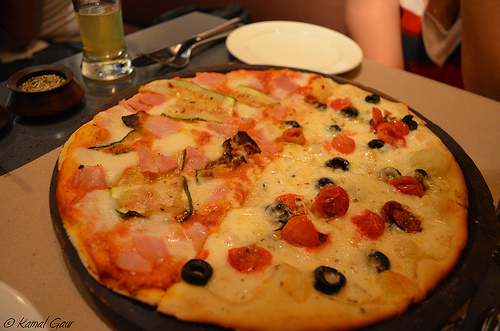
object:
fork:
[137, 32, 230, 67]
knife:
[128, 18, 240, 68]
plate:
[223, 20, 362, 76]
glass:
[75, 2, 133, 82]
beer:
[77, 2, 125, 56]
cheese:
[228, 211, 266, 243]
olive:
[181, 259, 214, 285]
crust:
[451, 211, 468, 257]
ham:
[143, 118, 182, 138]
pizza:
[57, 68, 471, 330]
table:
[0, 9, 500, 330]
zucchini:
[140, 78, 238, 124]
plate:
[0, 282, 48, 331]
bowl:
[5, 63, 84, 118]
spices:
[19, 74, 67, 92]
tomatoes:
[309, 184, 349, 219]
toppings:
[181, 120, 277, 175]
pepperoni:
[280, 215, 329, 250]